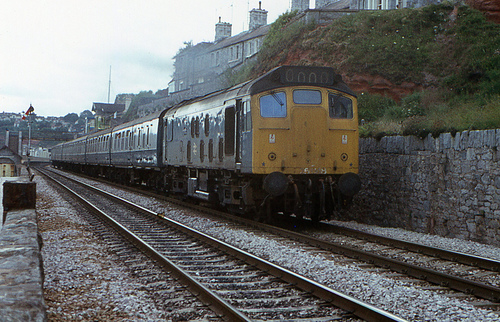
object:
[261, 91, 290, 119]
windshield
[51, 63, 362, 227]
train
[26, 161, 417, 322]
train tracks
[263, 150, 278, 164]
headlight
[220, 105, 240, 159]
door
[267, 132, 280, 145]
number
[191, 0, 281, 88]
building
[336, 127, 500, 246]
stone wall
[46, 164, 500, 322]
rocks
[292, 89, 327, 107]
windows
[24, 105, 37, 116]
flags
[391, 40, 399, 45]
small flowers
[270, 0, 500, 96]
hill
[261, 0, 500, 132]
grass